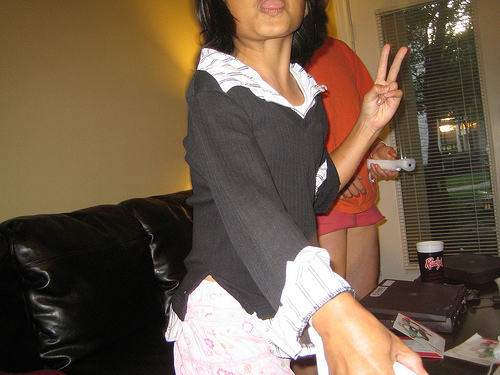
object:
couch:
[0, 187, 209, 374]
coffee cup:
[416, 238, 448, 282]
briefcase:
[356, 276, 473, 338]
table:
[357, 263, 498, 374]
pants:
[314, 202, 387, 239]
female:
[296, 35, 400, 303]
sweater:
[157, 45, 361, 351]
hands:
[338, 172, 367, 197]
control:
[366, 157, 415, 170]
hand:
[364, 144, 399, 181]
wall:
[1, 0, 336, 220]